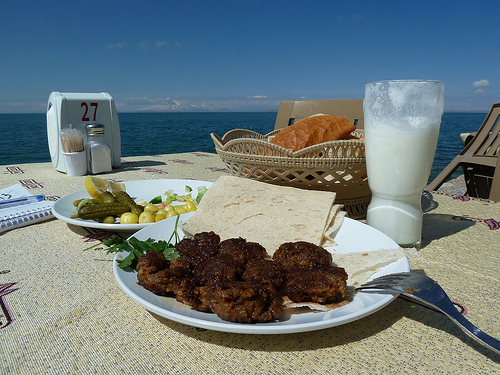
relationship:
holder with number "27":
[45, 91, 122, 173] [80, 101, 103, 127]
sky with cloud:
[0, 0, 497, 111] [473, 78, 490, 85]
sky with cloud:
[0, 0, 497, 111] [1, 92, 498, 111]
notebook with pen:
[0, 183, 58, 234] [14, 186, 64, 208]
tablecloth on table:
[2, 252, 110, 369] [7, 161, 113, 277]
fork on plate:
[353, 270, 498, 358] [126, 245, 352, 345]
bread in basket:
[241, 114, 357, 178] [209, 113, 370, 219]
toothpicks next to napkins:
[60, 127, 85, 177] [48, 87, 109, 119]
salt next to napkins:
[83, 121, 113, 174] [48, 87, 109, 119]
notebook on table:
[1, 181, 65, 237] [1, 154, 494, 374]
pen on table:
[0, 193, 47, 211] [1, 154, 494, 374]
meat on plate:
[136, 230, 348, 324] [112, 206, 409, 335]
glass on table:
[351, 74, 441, 253] [7, 270, 120, 373]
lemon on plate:
[83, 172, 127, 197] [53, 176, 211, 228]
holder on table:
[45, 91, 122, 173] [23, 210, 153, 368]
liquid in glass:
[369, 114, 448, 131] [349, 81, 435, 242]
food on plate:
[131, 246, 366, 316] [113, 207, 409, 336]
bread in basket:
[241, 111, 362, 178] [247, 112, 404, 199]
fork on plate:
[353, 270, 498, 358] [112, 206, 409, 335]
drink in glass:
[366, 116, 438, 244] [361, 74, 446, 252]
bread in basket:
[241, 114, 357, 178] [208, 104, 365, 191]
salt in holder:
[83, 121, 113, 174] [42, 88, 122, 175]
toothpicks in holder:
[56, 120, 84, 152] [42, 88, 122, 175]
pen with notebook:
[0, 193, 44, 207] [2, 180, 53, 237]